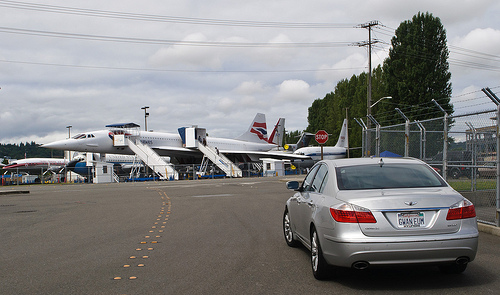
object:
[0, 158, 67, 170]
plane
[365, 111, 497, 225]
fence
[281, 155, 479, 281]
car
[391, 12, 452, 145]
trees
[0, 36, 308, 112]
clouds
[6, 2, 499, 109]
sky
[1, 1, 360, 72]
power lines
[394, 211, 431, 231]
license plate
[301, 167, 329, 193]
windows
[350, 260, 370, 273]
exhaust pipe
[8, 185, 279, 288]
road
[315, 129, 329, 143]
stop sign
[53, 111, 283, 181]
plane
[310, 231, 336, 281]
tire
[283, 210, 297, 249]
tire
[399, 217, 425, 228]
lettering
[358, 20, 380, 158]
pole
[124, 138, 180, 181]
ramp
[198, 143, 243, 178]
ramp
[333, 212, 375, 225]
tail light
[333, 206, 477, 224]
lights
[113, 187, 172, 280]
dots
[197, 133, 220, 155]
people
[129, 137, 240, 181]
ramps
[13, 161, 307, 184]
fence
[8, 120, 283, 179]
airplanes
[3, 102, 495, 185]
airport